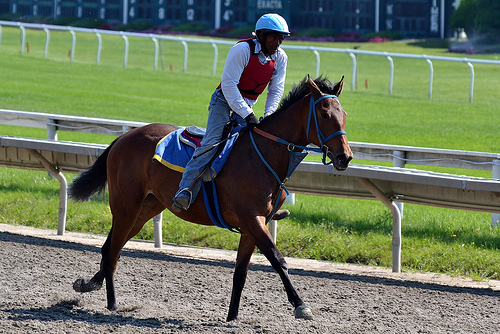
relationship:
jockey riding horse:
[170, 11, 290, 216] [66, 72, 353, 327]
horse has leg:
[66, 72, 353, 327] [88, 181, 151, 312]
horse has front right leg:
[66, 72, 353, 327] [236, 199, 316, 325]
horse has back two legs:
[66, 72, 353, 327] [73, 149, 163, 312]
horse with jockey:
[66, 72, 353, 327] [170, 11, 290, 216]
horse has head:
[66, 72, 353, 327] [304, 71, 355, 172]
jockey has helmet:
[170, 11, 290, 216] [253, 12, 291, 36]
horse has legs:
[66, 72, 353, 327] [71, 207, 315, 325]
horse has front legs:
[66, 72, 353, 327] [228, 203, 315, 326]